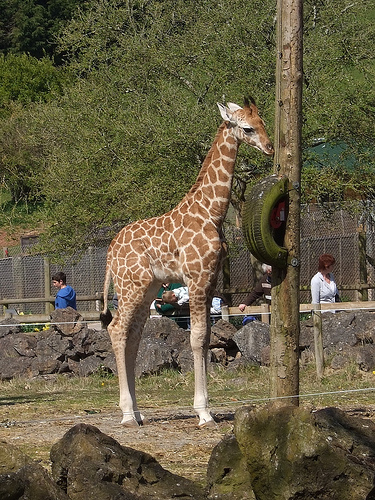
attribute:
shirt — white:
[309, 272, 339, 303]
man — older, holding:
[255, 259, 284, 321]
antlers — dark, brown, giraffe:
[243, 96, 254, 105]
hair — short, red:
[319, 254, 338, 271]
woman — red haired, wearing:
[304, 241, 349, 319]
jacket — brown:
[239, 274, 272, 305]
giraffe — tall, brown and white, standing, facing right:
[100, 90, 272, 411]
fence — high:
[1, 213, 112, 319]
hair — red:
[301, 247, 357, 272]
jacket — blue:
[52, 285, 75, 311]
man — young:
[50, 270, 76, 309]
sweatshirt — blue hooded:
[53, 285, 76, 309]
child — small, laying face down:
[145, 282, 218, 321]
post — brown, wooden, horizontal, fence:
[12, 290, 53, 331]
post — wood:
[264, 0, 305, 406]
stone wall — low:
[3, 310, 104, 374]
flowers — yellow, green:
[25, 324, 47, 332]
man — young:
[45, 260, 78, 316]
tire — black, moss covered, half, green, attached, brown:
[240, 176, 288, 266]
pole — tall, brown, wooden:
[267, 2, 305, 405]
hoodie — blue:
[51, 279, 81, 314]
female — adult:
[301, 250, 347, 317]